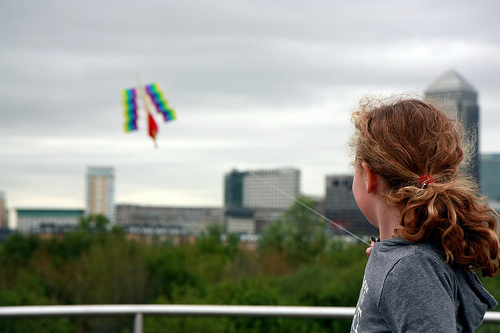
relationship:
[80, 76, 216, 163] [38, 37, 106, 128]
kite in air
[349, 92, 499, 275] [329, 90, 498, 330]
hair on person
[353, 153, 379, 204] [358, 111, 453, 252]
ear on person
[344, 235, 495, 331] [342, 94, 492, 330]
body on person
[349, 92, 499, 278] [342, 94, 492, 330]
hair on person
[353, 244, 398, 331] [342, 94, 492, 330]
chest on person